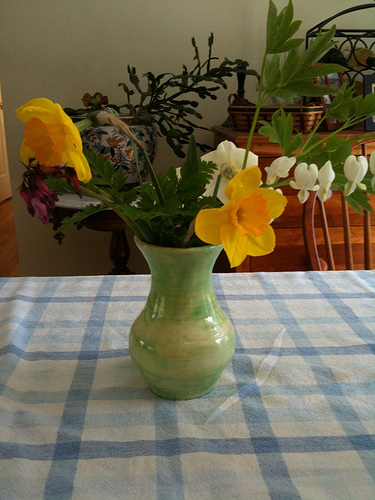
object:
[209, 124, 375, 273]
cabinet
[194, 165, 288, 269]
flower